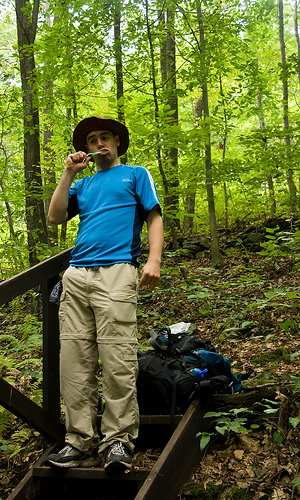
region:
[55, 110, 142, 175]
head of the man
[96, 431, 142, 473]
shoe on the man's foot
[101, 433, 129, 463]
laces on the shoe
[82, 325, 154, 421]
pant leg of the pants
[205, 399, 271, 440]
leaves next to man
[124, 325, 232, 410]
bags behind the man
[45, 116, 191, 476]
this is a man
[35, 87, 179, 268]
the man is brushing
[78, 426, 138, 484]
this is a sneaker shoe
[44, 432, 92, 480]
this is a sneaker shoe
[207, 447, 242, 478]
these are dead leaves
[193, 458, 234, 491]
these are dead leaves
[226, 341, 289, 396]
these are dead leaves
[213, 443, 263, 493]
these are dead leaves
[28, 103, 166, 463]
man wearing blue shirt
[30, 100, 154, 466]
man wearing tan pants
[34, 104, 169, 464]
man with toothbrush in his mouth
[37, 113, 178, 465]
man in the forest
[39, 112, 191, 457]
man standing on wood steps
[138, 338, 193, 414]
black bag on the ground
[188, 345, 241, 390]
blue bag on the ground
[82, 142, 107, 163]
green and blue toothbrush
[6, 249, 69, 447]
wood railing for steps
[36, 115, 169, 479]
teen boy brushing teeth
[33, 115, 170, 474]
teen boy standing on steps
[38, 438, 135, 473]
gray and white shoes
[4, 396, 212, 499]
wooden steps on hillside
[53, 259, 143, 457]
men's khaki cargo pants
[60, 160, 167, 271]
men's blue and white shirt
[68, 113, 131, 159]
casual hat on boy's head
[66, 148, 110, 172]
hand holding green toothbrush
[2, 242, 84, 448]
wooden stair rail beside boy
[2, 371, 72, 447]
wooden support brace on stair rail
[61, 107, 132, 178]
a man brushing his teeth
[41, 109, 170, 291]
a young man wearing a blue T-shirt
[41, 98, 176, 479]
a guy wearing beige pants and a blue T-shirt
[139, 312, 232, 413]
a black backpack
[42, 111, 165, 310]
a guy with a blue bandana in his pocket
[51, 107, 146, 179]
a guy wearing a hat brushing his teeth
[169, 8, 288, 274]
some trees in the forest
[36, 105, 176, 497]
a guy standing on a set of stairs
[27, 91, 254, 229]
a young man brushing his teeth in the forest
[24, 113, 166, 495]
a boy brushing his teeth while standing on the stairs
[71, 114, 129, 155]
Dark hat on a man's head.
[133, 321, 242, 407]
Large black pack on the steps.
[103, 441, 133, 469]
A man's left grey sneaker with white laces.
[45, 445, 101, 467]
A man's right grey sneaker.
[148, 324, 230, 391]
backpack on the ground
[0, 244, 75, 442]
Railing of a stairway in the woods.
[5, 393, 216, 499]
Stairway in the woods without its railing.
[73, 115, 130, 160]
Round-brimmed hat worn on a man.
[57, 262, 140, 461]
Khaki pants worn on a man.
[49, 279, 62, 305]
Dark handkerchief extruding from pants pocket.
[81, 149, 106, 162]
Green toothbrush in man's hand and mouth.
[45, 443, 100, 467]
Grey shoe worn on man's right foot.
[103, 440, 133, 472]
Grey shoe worn on man's left foot.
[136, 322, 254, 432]
Pile of backpacks behind a man.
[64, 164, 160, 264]
a blue and black shirt